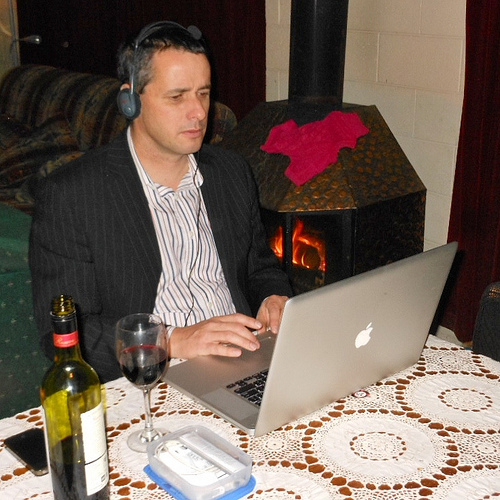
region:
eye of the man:
[163, 89, 183, 101]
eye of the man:
[190, 86, 204, 99]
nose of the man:
[190, 114, 212, 124]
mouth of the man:
[164, 125, 204, 143]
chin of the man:
[159, 137, 204, 161]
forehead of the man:
[133, 42, 208, 85]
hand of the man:
[175, 315, 260, 374]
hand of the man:
[255, 290, 282, 335]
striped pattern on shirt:
[157, 235, 226, 277]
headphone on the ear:
[118, 97, 143, 120]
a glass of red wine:
[109, 298, 177, 460]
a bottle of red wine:
[34, 280, 114, 497]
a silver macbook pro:
[155, 230, 460, 429]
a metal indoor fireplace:
[210, 1, 425, 289]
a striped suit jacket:
[13, 109, 308, 340]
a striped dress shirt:
[143, 125, 236, 370]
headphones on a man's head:
[108, 18, 218, 160]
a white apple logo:
[352, 319, 376, 349]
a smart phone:
[1, 410, 68, 477]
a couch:
[0, 52, 240, 230]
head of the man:
[101, 17, 231, 183]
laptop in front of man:
[186, 240, 464, 442]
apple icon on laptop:
[329, 313, 389, 369]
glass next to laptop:
[103, 303, 191, 429]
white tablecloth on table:
[313, 388, 470, 488]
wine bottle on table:
[11, 294, 117, 455]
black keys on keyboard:
[215, 364, 272, 416]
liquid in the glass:
[107, 332, 171, 397]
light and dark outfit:
[86, 164, 256, 297]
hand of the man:
[151, 288, 274, 405]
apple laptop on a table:
[161, 235, 469, 437]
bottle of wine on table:
[21, 282, 126, 498]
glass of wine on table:
[105, 308, 180, 461]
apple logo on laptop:
[345, 324, 382, 355]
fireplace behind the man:
[231, 90, 438, 324]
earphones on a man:
[102, 74, 145, 129]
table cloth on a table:
[358, 389, 498, 489]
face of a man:
[109, 24, 232, 166]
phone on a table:
[1, 423, 56, 480]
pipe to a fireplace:
[279, 6, 366, 111]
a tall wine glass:
[112, 315, 173, 450]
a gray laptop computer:
[166, 238, 462, 433]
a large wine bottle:
[45, 290, 112, 498]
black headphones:
[117, 20, 169, 125]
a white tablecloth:
[1, 333, 498, 498]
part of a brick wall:
[361, 3, 443, 108]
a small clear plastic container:
[147, 424, 246, 497]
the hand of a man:
[159, 308, 265, 359]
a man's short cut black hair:
[112, 25, 209, 95]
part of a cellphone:
[8, 423, 54, 474]